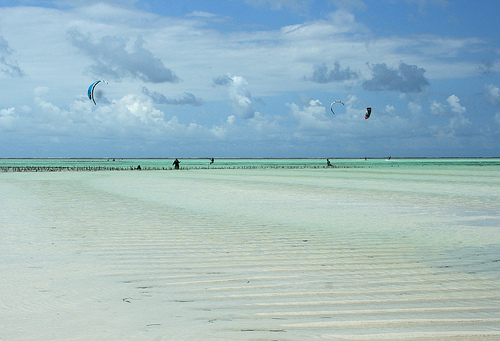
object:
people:
[326, 159, 334, 168]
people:
[113, 158, 115, 161]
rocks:
[67, 167, 71, 171]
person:
[210, 157, 215, 164]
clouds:
[360, 60, 428, 94]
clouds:
[139, 86, 205, 106]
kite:
[330, 100, 344, 114]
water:
[0, 157, 498, 339]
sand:
[2, 170, 498, 339]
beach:
[0, 170, 499, 339]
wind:
[145, 101, 351, 299]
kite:
[364, 107, 372, 119]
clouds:
[63, 24, 185, 84]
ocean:
[0, 156, 499, 169]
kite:
[87, 79, 103, 105]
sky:
[0, 0, 500, 160]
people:
[171, 158, 181, 169]